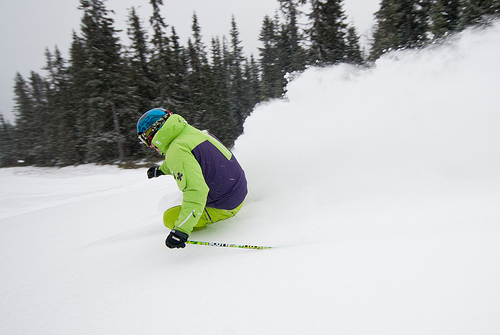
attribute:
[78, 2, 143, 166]
tree — tall, snow covered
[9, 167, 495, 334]
ground — covered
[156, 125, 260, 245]
person — wearing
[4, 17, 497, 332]
snow — tall , White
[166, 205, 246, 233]
pants — green 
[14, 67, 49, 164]
tree — tall, snow covered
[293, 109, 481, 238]
snow — white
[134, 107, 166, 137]
person's helmet — blue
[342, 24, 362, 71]
tree — tall, snow covered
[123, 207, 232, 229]
pants — green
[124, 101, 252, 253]
person — wearing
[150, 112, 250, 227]
jacket — blue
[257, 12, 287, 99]
tree — covered by snow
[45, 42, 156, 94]
trees — large